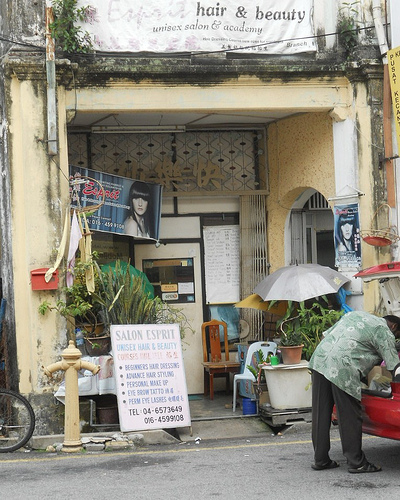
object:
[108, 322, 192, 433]
sign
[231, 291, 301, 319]
umbrella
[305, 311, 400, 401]
green shirt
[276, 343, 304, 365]
pot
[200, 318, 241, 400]
chair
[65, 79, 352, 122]
ground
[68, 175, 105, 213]
wheel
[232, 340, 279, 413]
patio chair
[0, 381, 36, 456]
bike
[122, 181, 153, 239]
girl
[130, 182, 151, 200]
bangs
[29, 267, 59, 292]
receptacle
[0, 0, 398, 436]
building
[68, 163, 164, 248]
banner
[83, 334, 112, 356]
pot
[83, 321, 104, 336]
pot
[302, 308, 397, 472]
man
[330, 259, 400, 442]
car trunk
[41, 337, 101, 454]
fire hydrant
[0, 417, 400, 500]
ground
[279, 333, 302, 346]
red plant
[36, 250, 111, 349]
red plant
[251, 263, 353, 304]
umbrellas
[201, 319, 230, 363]
back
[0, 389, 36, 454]
tire